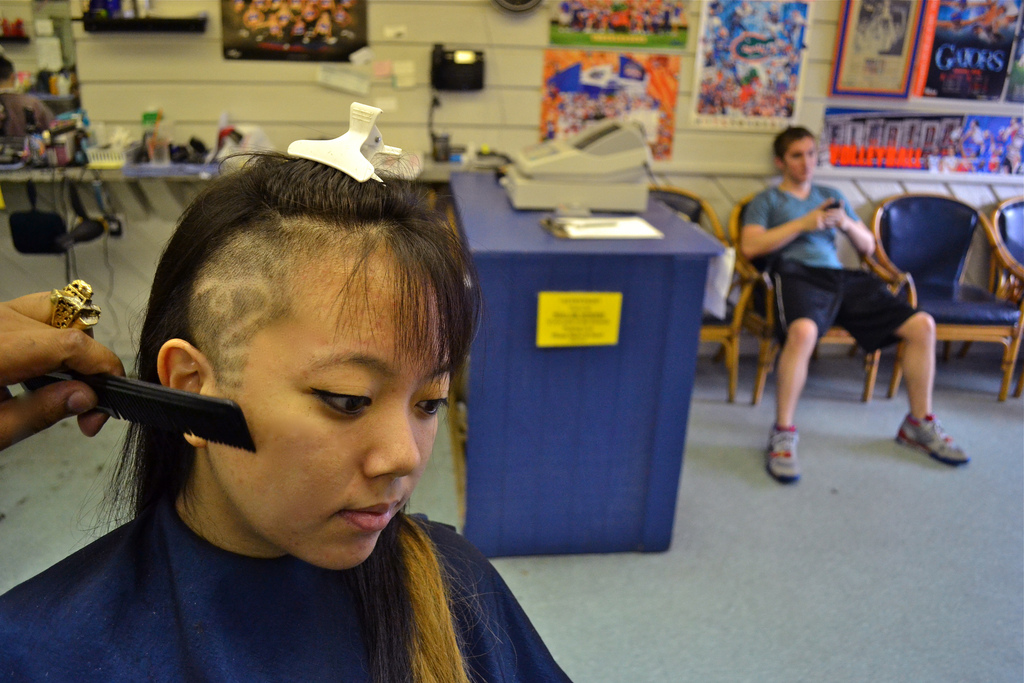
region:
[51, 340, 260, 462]
comb beside woman's face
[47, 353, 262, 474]
comb in hand is black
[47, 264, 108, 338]
ring on man's hand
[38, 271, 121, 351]
ring on hand is gold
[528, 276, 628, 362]
sign attached to counter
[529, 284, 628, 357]
sign on counter is yellow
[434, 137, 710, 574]
counter by chairs is blue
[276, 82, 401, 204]
clip in woman's hair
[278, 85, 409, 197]
clip in hair is white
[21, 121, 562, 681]
person cutting the hair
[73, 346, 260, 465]
the comb is color black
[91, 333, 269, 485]
comb on front an ear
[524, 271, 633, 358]
the board is yellow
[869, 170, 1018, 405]
the chair is blue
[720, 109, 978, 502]
man sits on a chair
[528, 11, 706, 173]
poster on the wall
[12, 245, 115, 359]
a ring on a finger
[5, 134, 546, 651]
the woman is getting her hair cut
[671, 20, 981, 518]
a boy is sitting in a chair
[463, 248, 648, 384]
the sign is square shaped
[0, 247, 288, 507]
a person is holding a comb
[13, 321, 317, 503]
the comb is black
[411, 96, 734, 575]
the desk is blue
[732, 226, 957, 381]
the boy is wearing shorts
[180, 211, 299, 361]
woman with a half shaved head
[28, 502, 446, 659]
woman wearing a blue cloth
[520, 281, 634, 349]
yellow sign on the counter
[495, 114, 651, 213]
cash register on the table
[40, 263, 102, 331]
man wearing a gold ring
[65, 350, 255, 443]
person holding a black comb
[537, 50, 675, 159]
poster hanging on the wall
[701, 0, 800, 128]
poster hanging on the wall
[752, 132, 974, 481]
a man sitting on a chair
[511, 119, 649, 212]
a white cash register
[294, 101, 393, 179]
a white hair clip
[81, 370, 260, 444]
a black comb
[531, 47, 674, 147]
a poster on the wall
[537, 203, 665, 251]
papers on the counter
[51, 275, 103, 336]
a gold ring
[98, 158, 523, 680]
a girl who is getting her hair cut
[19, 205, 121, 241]
a small black chair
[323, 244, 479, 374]
bangs on a forehead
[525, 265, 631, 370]
sign on the counter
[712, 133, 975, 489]
man in the background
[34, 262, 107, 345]
ring on a finger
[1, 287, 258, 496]
person holding a comb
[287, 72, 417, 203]
a white hair clip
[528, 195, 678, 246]
clip board on the counter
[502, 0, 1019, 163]
posters on the wall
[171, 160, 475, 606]
the head of a woman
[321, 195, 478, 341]
the hair of a woman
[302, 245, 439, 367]
the forehead of a woman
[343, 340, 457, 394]
the brows of a woman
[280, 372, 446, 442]
the eyes of a woman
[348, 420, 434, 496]
the nose of a woman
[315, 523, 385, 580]
the chin of a woman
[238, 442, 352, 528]
the cheek of a woman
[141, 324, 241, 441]
the ear of a woman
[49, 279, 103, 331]
gold ring on man's hand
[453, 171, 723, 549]
blue counter made of wood